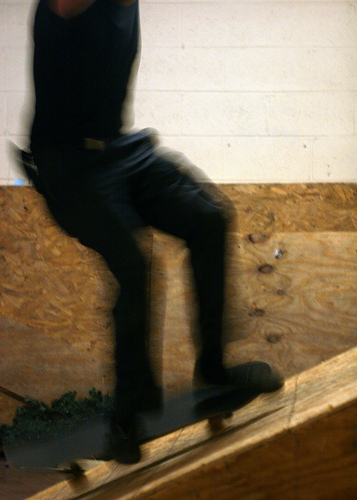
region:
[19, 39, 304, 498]
skateboarder skating on ramp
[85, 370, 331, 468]
skateboard on man's feet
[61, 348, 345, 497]
wood ramp under man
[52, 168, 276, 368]
tight jeans on man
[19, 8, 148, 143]
dark t shirt on man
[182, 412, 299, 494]
shadow of board on ramp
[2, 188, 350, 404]
wood wall on side of ramp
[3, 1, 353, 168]
white brick wall of park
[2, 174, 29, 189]
blue sticker on white wall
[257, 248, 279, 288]
brown knots in wood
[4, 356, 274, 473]
a skateboard under a man's feet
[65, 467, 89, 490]
wheel of a skateboard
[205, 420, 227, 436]
wheel of a skateboard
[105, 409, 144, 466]
a man's black shoe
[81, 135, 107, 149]
a man's black buckle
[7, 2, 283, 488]
a man is on a skateboard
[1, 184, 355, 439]
wood against a wall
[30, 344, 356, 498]
a wooden ramp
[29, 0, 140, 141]
a man's black shirt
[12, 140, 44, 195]
something in a man's pocket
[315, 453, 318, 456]
part of a bench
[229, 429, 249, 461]
edge of a bench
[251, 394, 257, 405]
part of a sock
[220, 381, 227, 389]
edge of a sock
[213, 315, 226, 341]
part of a trouser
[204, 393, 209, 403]
edge of a foot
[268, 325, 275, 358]
part of a table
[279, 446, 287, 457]
edge of a table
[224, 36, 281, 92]
this is the wall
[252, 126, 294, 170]
the wall is wooden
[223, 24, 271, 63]
the wall is white in color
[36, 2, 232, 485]
this is a man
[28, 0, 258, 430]
the man is on the surfboard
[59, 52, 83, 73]
this is a t-shirt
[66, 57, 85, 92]
the t-shirt is black in color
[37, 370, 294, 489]
this is a skateboard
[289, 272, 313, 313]
the area is brown in color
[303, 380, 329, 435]
the area is slopy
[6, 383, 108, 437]
green grass in corner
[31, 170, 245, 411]
man wearing blue jeans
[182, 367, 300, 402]
man wearing black sneakers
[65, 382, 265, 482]
man riding skateboard indoors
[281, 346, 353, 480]
man made skate ramp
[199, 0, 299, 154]
wall painted in white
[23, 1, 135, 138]
black short sleeve shirt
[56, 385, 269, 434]
man standing on skateboard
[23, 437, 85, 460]
grey pavement at park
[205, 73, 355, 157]
white paint on wall